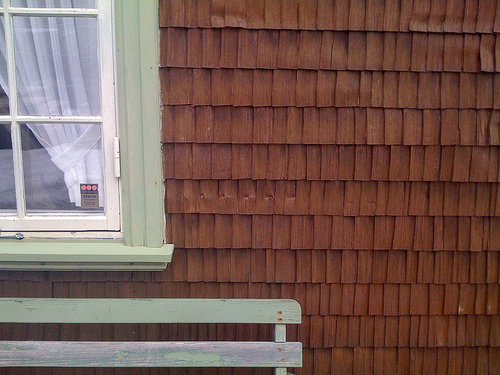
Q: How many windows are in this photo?
A: One.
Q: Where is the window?
A: On the left.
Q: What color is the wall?
A: Red.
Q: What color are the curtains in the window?
A: White.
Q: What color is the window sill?
A: Green.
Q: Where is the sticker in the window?
A: In the lower right hand quadrant.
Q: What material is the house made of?
A: Wood.